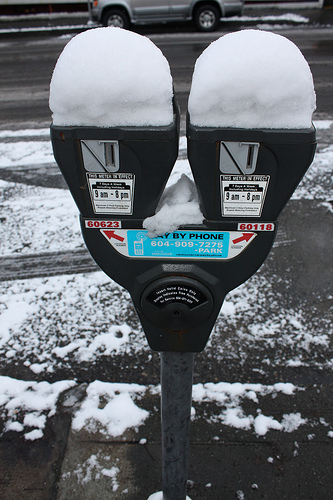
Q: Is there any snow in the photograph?
A: Yes, there is snow.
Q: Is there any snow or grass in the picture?
A: Yes, there is snow.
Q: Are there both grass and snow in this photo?
A: No, there is snow but no grass.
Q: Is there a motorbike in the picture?
A: No, there are no motorcycles.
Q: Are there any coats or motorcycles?
A: No, there are no motorcycles or coats.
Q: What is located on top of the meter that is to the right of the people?
A: The snow is on top of the parking meter.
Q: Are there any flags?
A: No, there are no flags.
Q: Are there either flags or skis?
A: No, there are no flags or skis.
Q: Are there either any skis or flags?
A: No, there are no flags or skis.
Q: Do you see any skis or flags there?
A: No, there are no flags or skis.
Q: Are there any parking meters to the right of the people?
A: Yes, there is a parking meter to the right of the people.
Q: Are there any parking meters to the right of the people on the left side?
A: Yes, there is a parking meter to the right of the people.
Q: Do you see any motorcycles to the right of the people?
A: No, there is a parking meter to the right of the people.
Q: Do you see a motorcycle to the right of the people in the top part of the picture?
A: No, there is a parking meter to the right of the people.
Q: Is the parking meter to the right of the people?
A: Yes, the parking meter is to the right of the people.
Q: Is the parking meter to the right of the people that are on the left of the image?
A: Yes, the parking meter is to the right of the people.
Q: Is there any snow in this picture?
A: Yes, there is snow.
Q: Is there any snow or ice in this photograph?
A: Yes, there is snow.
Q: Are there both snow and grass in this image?
A: No, there is snow but no grass.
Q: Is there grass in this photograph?
A: No, there is no grass.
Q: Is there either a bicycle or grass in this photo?
A: No, there are no grass or bicycles.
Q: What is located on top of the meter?
A: The snow is on top of the meter.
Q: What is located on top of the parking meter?
A: The snow is on top of the meter.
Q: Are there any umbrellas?
A: No, there are no umbrellas.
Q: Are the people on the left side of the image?
A: Yes, the people are on the left of the image.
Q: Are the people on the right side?
A: No, the people are on the left of the image.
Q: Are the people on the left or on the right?
A: The people are on the left of the image.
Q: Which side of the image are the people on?
A: The people are on the left of the image.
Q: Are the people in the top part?
A: Yes, the people are in the top of the image.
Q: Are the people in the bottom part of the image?
A: No, the people are in the top of the image.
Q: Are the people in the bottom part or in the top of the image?
A: The people are in the top of the image.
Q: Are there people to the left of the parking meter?
A: Yes, there are people to the left of the parking meter.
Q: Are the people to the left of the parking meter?
A: Yes, the people are to the left of the parking meter.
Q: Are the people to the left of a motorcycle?
A: No, the people are to the left of the parking meter.